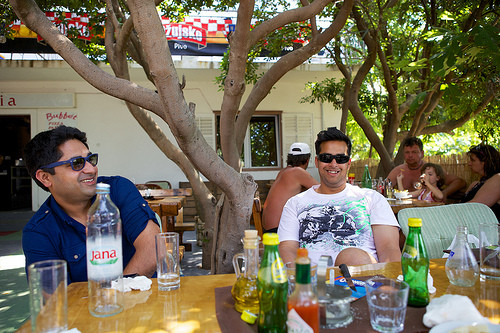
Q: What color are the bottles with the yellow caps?
A: Green.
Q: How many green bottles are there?
A: 2.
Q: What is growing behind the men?
A: Tree.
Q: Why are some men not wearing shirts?
A: It's hot.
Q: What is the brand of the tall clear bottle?
A: Jana.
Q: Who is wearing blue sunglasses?
A: The man on left.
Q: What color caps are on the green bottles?
A: Yellow.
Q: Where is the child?
A: In the back right.